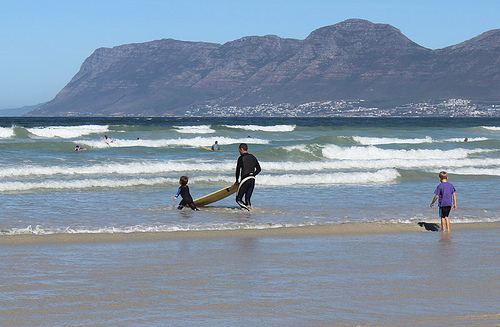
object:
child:
[428, 170, 459, 232]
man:
[232, 143, 263, 213]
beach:
[0, 194, 500, 326]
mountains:
[25, 18, 500, 117]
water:
[2, 117, 500, 187]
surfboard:
[183, 181, 239, 207]